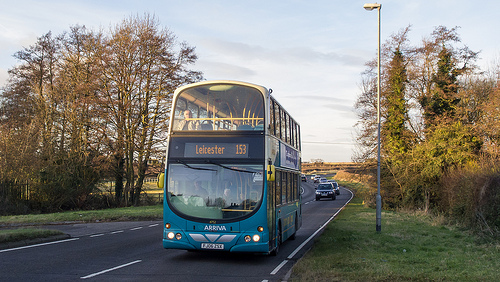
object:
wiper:
[183, 164, 218, 172]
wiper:
[215, 163, 258, 174]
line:
[81, 255, 142, 280]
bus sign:
[190, 144, 249, 155]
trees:
[351, 21, 419, 210]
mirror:
[264, 166, 274, 181]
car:
[312, 182, 334, 200]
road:
[0, 223, 158, 237]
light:
[360, 2, 380, 11]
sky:
[0, 1, 499, 162]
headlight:
[166, 231, 174, 238]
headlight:
[253, 234, 260, 241]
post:
[374, 5, 382, 234]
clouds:
[317, 103, 370, 121]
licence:
[201, 242, 223, 249]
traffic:
[297, 166, 351, 209]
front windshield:
[165, 161, 264, 220]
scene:
[0, 0, 499, 282]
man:
[175, 110, 201, 132]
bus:
[156, 80, 304, 258]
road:
[0, 173, 350, 281]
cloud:
[194, 61, 262, 80]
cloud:
[280, 93, 357, 106]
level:
[158, 80, 302, 159]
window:
[168, 161, 270, 223]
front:
[160, 81, 268, 253]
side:
[282, 183, 358, 282]